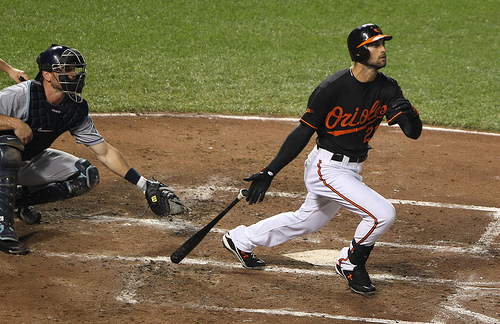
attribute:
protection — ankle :
[345, 231, 379, 265]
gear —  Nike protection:
[10, 42, 104, 211]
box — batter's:
[127, 110, 482, 321]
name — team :
[323, 96, 393, 141]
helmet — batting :
[344, 20, 391, 58]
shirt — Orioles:
[277, 66, 406, 161]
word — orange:
[324, 101, 388, 136]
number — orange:
[364, 125, 379, 142]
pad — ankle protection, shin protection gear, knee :
[345, 234, 378, 269]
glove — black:
[144, 176, 192, 218]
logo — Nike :
[37, 125, 53, 137]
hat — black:
[344, 22, 390, 64]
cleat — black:
[219, 234, 267, 270]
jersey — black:
[295, 64, 424, 163]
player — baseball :
[216, 9, 442, 301]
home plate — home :
[282, 244, 340, 269]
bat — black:
[164, 184, 249, 267]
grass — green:
[114, 6, 289, 99]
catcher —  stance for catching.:
[4, 40, 187, 257]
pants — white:
[221, 142, 400, 299]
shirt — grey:
[1, 77, 108, 154]